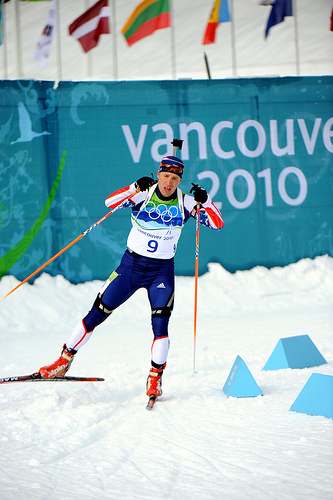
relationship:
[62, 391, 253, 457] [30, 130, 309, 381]
snow on mountain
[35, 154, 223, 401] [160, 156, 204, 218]
man has face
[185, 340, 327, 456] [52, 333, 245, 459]
ice for skating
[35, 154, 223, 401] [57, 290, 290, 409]
man has legs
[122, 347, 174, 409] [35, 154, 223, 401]
shoe on man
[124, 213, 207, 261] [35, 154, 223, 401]
number on man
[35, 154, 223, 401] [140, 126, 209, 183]
man has cap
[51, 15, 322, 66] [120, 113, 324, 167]
flags over vancouver